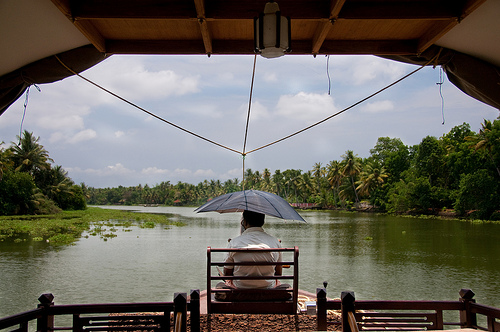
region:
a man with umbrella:
[177, 161, 311, 321]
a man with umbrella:
[178, 158, 286, 326]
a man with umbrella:
[177, 162, 279, 329]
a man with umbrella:
[192, 164, 306, 330]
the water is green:
[330, 207, 410, 295]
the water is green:
[310, 230, 407, 274]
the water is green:
[358, 254, 433, 291]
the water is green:
[316, 212, 452, 292]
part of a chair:
[245, 255, 273, 310]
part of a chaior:
[251, 285, 267, 308]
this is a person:
[205, 196, 296, 318]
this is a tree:
[310, 153, 355, 213]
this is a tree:
[348, 131, 410, 208]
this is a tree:
[24, 158, 88, 233]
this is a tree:
[310, 146, 358, 198]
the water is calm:
[77, 203, 152, 285]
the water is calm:
[311, 211, 386, 293]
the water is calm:
[110, 219, 172, 301]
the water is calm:
[372, 211, 457, 296]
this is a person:
[198, 212, 294, 307]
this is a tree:
[352, 122, 397, 214]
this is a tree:
[408, 135, 433, 221]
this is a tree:
[450, 126, 490, 229]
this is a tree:
[10, 126, 68, 236]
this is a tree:
[135, 186, 183, 211]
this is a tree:
[295, 165, 358, 225]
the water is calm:
[113, 220, 151, 280]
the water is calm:
[326, 231, 405, 280]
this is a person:
[211, 201, 292, 303]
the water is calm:
[344, 221, 396, 279]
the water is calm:
[125, 223, 182, 287]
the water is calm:
[68, 222, 140, 289]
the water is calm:
[288, 218, 372, 298]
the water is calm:
[391, 233, 468, 300]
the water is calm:
[124, 199, 196, 300]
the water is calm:
[57, 238, 129, 302]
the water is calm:
[300, 209, 382, 274]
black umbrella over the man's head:
[192, 185, 307, 226]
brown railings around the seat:
[17, 277, 474, 331]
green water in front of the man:
[8, 190, 498, 311]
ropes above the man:
[57, 52, 443, 189]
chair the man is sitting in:
[202, 241, 304, 328]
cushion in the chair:
[212, 275, 289, 299]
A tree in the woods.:
[393, 164, 428, 211]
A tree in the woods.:
[366, 135, 421, 202]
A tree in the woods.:
[364, 159, 398, 196]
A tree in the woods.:
[343, 147, 373, 204]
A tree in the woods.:
[330, 167, 355, 207]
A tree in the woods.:
[312, 163, 336, 208]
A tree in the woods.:
[291, 166, 306, 201]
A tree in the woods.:
[259, 165, 286, 197]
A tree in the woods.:
[244, 166, 259, 196]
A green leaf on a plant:
[420, 148, 422, 150]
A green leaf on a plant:
[23, 178, 24, 180]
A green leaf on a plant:
[56, 173, 59, 177]